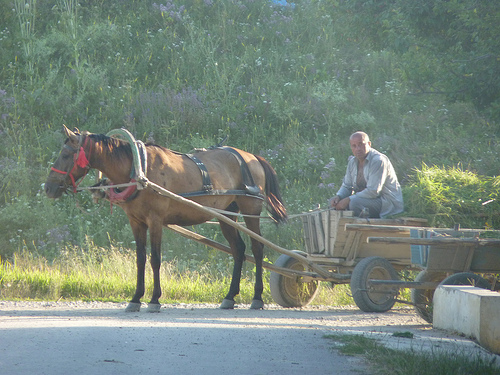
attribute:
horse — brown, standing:
[52, 140, 261, 316]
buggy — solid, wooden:
[275, 212, 490, 302]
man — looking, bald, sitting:
[332, 130, 403, 217]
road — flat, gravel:
[76, 306, 106, 328]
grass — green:
[435, 181, 456, 199]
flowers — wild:
[263, 88, 266, 99]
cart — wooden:
[416, 232, 490, 263]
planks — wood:
[419, 255, 424, 262]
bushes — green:
[12, 46, 25, 72]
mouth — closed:
[51, 180, 62, 198]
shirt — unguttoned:
[365, 159, 379, 173]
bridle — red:
[76, 151, 89, 169]